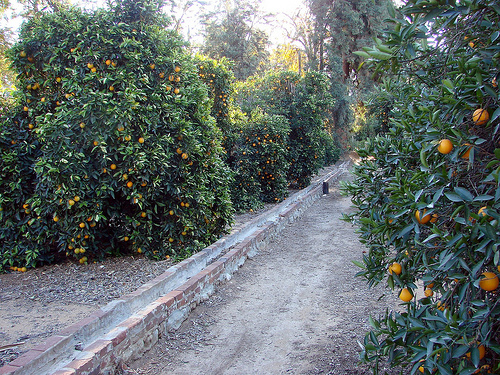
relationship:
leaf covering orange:
[426, 142, 441, 151] [434, 137, 456, 157]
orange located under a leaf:
[434, 137, 456, 157] [369, 49, 396, 61]